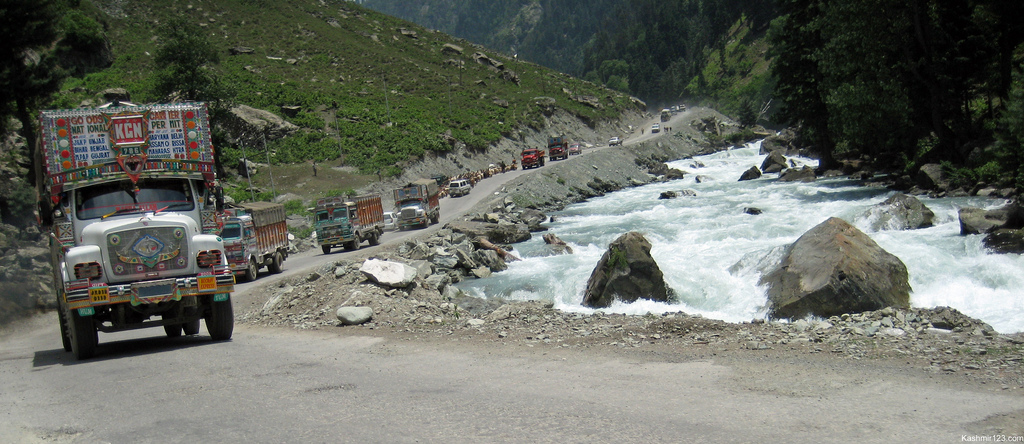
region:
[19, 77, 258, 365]
THE TRUCK IS BIG AND COLORFUL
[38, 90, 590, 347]
THE CARS ARE ALL ON THE ROAD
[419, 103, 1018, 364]
THE RIVER IS NEXT TO THE ROAD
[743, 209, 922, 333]
THE BOULDER IS BROWN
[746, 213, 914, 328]
THE BOLDER IS IN THE WATER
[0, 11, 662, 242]
THE HILL IS LUSH AND GREEN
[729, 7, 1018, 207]
THE TREES ARE LUSH AND GREEN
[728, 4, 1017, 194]
THE TREES ARE LEAFY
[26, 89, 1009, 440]
THE ROAD IS DIRT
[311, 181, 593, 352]
MANY ROCKS ARE ON THE SIDE OF THE ROAD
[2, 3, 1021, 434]
a scene during the day time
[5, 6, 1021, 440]
a scene outside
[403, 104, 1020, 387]
a choppy river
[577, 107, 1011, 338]
large gray rocks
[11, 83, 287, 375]
a large white truck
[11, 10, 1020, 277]
green hills in the background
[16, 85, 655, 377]
row of vehicles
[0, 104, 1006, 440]
curved gray road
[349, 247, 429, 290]
a white rock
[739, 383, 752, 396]
a piece of image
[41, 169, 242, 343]
a car on a street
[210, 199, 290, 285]
a car on a street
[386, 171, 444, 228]
a car on a street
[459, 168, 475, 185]
a car on a street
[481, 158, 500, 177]
a car on a street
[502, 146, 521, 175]
a car on a street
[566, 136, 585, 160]
a car on a street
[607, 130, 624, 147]
a car on a street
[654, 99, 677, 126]
a car on a street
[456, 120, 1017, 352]
Water rushing down a river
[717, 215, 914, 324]
Large stone boulder in a river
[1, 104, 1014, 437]
Winding mountain road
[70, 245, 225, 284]
Front lights on a truck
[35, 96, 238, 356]
Multicolored and decorated truck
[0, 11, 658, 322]
Grass and rock covered mountainside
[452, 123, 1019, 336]
White caps caused by flowing water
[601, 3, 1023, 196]
Tree covered river bank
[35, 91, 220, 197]
Advertisement covering top of a truck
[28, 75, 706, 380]
Line of traffic on a mountain road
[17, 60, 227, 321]
large truck on road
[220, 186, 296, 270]
large truck on road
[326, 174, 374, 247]
large truck on road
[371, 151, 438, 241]
large truck on road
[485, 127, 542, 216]
large truck on road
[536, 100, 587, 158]
large truck on road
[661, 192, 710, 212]
waves in white and green water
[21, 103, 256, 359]
vehicle by the raging river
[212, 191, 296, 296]
vehicle by the raging river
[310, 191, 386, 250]
vehicle by the raging river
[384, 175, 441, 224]
vehicle by the raging river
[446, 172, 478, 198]
vehicle by the raging river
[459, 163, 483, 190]
vehicle by the raging river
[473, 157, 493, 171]
vehicle by the raging river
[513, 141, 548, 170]
vehicle by the raging river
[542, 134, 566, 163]
vehicle by the raging river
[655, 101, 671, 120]
vehicle by the raging river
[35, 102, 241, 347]
the truck is on the road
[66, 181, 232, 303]
the truck is painted white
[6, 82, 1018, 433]
the road runs besides a river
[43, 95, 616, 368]
a caravan of trucks is on the road